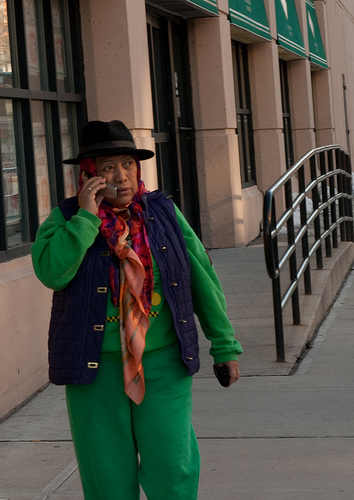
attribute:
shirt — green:
[70, 212, 216, 377]